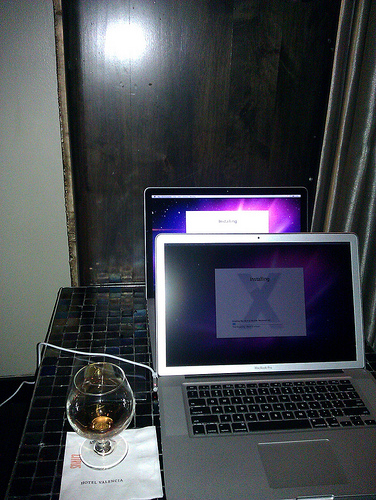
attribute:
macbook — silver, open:
[151, 231, 360, 498]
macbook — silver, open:
[141, 183, 311, 373]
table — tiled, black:
[4, 283, 362, 498]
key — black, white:
[191, 423, 206, 435]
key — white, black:
[188, 404, 213, 414]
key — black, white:
[210, 386, 222, 397]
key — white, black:
[212, 406, 223, 413]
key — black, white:
[230, 411, 245, 422]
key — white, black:
[233, 386, 247, 394]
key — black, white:
[248, 402, 260, 412]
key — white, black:
[278, 394, 291, 402]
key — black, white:
[326, 382, 337, 393]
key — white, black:
[295, 400, 310, 410]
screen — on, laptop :
[165, 238, 353, 362]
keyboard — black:
[176, 377, 364, 443]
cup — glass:
[59, 357, 154, 476]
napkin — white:
[59, 425, 163, 496]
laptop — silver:
[151, 234, 374, 497]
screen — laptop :
[159, 237, 364, 379]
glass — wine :
[52, 361, 132, 464]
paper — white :
[65, 467, 153, 497]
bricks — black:
[65, 297, 138, 351]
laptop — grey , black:
[157, 228, 362, 485]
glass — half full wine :
[67, 367, 138, 472]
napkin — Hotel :
[65, 475, 147, 495]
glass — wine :
[68, 364, 143, 478]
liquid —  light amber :
[76, 403, 119, 433]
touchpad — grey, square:
[257, 430, 356, 489]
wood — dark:
[53, 0, 373, 295]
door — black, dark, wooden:
[51, 2, 373, 289]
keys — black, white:
[182, 376, 367, 438]